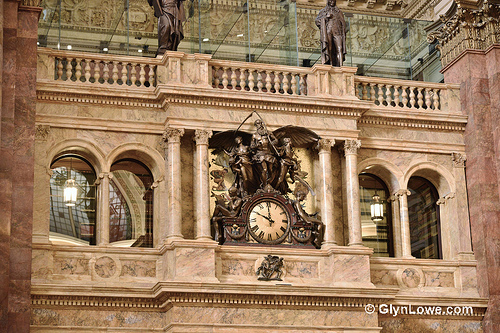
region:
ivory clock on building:
[251, 201, 288, 242]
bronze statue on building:
[220, 110, 302, 189]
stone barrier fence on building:
[37, 47, 469, 116]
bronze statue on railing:
[315, 1, 348, 70]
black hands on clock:
[256, 204, 276, 224]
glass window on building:
[52, 162, 133, 241]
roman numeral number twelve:
[266, 204, 272, 208]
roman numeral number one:
[273, 204, 278, 209]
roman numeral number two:
[280, 209, 285, 216]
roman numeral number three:
[281, 218, 289, 224]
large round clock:
[243, 193, 297, 243]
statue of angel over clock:
[205, 108, 321, 192]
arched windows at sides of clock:
[40, 129, 169, 249]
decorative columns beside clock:
[162, 122, 217, 249]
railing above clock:
[163, 64, 353, 96]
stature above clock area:
[311, 0, 352, 65]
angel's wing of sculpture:
[266, 123, 319, 148]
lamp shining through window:
[55, 166, 95, 219]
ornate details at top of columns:
[419, 1, 499, 68]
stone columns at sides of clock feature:
[1, 60, 41, 315]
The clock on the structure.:
[247, 193, 289, 242]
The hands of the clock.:
[256, 203, 276, 224]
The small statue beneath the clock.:
[249, 250, 286, 278]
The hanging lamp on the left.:
[63, 166, 75, 207]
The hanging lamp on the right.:
[371, 165, 383, 225]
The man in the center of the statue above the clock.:
[247, 109, 283, 187]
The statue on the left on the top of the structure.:
[151, 0, 187, 48]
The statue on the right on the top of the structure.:
[319, 3, 349, 58]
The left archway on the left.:
[56, 141, 102, 241]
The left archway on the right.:
[362, 161, 397, 248]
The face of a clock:
[245, 198, 290, 243]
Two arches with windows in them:
[46, 140, 164, 250]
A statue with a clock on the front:
[208, 109, 326, 249]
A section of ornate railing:
[38, 48, 463, 118]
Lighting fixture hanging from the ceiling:
[61, 157, 76, 204]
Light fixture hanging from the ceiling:
[370, 186, 385, 217]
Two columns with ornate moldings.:
[160, 125, 215, 245]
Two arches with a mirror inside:
[353, 155, 452, 262]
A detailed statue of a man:
[316, 0, 348, 67]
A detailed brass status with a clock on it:
[208, 112, 327, 248]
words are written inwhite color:
[369, 272, 498, 322]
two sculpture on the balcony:
[146, 0, 385, 75]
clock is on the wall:
[226, 134, 346, 253]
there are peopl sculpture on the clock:
[216, 138, 344, 264]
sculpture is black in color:
[306, 2, 364, 69]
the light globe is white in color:
[364, 197, 412, 228]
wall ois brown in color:
[440, 111, 487, 238]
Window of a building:
[401, 177, 446, 260]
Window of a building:
[354, 168, 396, 260]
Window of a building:
[107, 159, 158, 248]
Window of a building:
[47, 150, 102, 246]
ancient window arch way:
[99, 136, 159, 251]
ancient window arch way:
[36, 130, 108, 254]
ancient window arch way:
[350, 159, 400, 267]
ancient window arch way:
[403, 165, 453, 267]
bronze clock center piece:
[218, 113, 313, 248]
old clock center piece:
[204, 107, 324, 253]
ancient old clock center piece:
[208, 111, 323, 251]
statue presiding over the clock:
[313, 4, 354, 68]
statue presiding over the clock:
[150, 0, 197, 54]